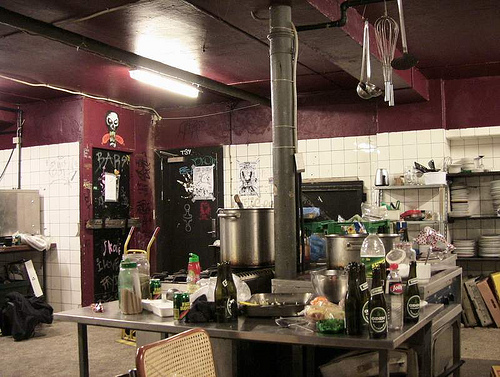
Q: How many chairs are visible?
A: One.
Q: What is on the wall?
A: Tile.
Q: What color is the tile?
A: White.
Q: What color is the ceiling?
A: Maroon.